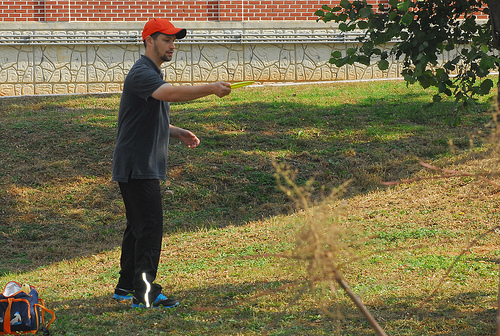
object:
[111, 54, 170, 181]
shirt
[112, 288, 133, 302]
shoes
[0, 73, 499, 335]
ground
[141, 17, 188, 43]
hat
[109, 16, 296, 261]
playing frisbee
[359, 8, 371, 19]
leaves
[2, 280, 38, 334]
bag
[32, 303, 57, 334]
orange straps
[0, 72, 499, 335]
grass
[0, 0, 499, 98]
wall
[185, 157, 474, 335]
limb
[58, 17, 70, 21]
brick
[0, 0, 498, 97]
building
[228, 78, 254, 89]
frisbee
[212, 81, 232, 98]
hand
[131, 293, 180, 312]
shoes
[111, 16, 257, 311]
man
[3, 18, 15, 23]
red brick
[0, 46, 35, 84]
fake stone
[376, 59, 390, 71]
leaves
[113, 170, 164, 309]
pants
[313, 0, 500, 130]
tree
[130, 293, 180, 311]
feet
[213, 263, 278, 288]
dirt